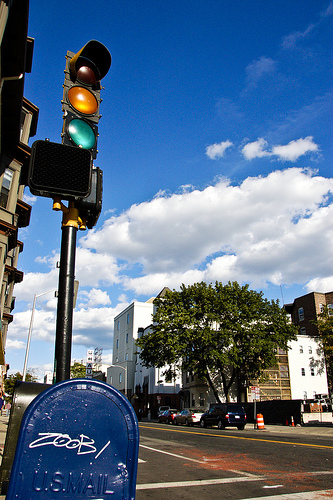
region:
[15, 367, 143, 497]
a blue US Mail Post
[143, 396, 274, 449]
the cars are parked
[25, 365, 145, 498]
blue mailbox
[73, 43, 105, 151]
signal light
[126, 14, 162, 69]
white clouds in blue sky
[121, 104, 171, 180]
white clouds in blue sky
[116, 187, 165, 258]
white clouds in blue sky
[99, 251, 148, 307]
white clouds in blue sky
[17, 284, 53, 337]
white clouds in blue sky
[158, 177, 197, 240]
white clouds in blue sky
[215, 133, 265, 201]
white clouds in blue sky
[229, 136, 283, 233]
white clouds in blue sky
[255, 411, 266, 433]
orange traffic cone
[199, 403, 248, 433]
parked black SUV on the side of the road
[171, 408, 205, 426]
parked gray car on the side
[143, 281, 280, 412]
gorgeous looking tree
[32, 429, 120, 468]
graffiti painted on the side of a mailbox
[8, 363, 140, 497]
blue mailbox for the US mail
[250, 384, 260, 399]
A no parking sign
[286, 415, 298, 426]
Another street cone, smaller version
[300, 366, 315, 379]
Open windows, residents are getting some fresh air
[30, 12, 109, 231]
Traffic light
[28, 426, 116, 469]
White lettering on mailbox says zoob!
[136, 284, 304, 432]
Large bushy green tree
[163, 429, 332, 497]
red clay dirt in the middle of the road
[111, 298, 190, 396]
Large white building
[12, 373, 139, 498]
Small blue mailbox in foreground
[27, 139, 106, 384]
Large black metal pole behind mailbox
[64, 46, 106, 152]
Streetlight on black pole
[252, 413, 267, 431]
Orange and white cone on sidewalk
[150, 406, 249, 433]
Row of cars parked on curb.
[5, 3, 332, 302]
Blue cloudy sky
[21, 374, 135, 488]
mailbox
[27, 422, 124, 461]
graffiti on mailbox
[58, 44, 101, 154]
traffic signal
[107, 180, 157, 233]
white clouds in blue sky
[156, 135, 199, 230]
white clouds in blue sky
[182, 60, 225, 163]
white clouds in blue sky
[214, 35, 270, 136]
white clouds in blue sky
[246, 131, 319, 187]
white clouds in blue sky